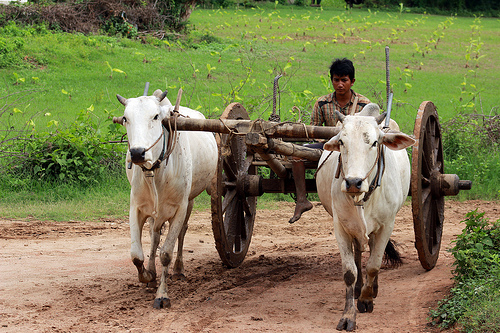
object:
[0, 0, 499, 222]
field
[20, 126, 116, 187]
plant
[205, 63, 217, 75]
plant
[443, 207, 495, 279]
plant